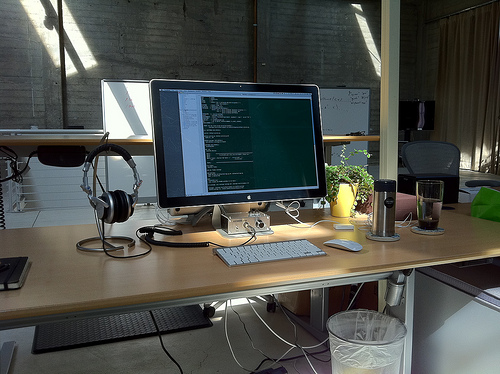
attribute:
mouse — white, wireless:
[323, 237, 364, 253]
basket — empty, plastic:
[323, 307, 406, 374]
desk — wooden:
[1, 182, 498, 326]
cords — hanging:
[208, 281, 370, 373]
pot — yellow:
[326, 178, 359, 219]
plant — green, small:
[324, 149, 373, 204]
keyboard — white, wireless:
[210, 238, 326, 266]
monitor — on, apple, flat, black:
[148, 76, 329, 207]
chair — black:
[398, 139, 460, 204]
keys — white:
[226, 242, 315, 259]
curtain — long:
[435, 0, 498, 179]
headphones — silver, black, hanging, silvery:
[80, 142, 142, 223]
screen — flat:
[157, 86, 317, 190]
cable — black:
[146, 306, 187, 373]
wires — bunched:
[137, 205, 336, 248]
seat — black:
[404, 180, 471, 204]